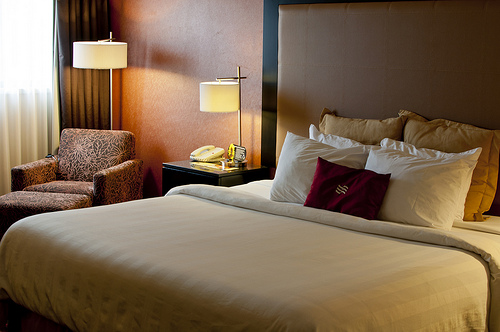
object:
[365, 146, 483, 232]
pillow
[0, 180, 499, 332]
bed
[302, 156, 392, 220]
pillow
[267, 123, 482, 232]
pillow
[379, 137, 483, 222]
pillow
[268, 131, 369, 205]
pillow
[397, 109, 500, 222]
pillow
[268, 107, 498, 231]
pillow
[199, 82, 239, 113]
lamp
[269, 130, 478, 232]
pillow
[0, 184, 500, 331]
blanket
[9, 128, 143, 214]
chair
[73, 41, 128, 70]
lamp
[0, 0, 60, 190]
curtains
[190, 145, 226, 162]
telephone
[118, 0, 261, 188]
wall